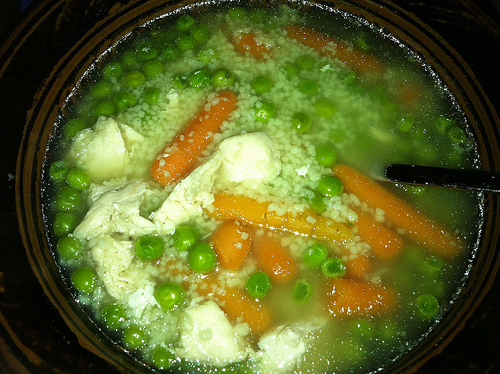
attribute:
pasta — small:
[71, 110, 315, 372]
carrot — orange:
[145, 82, 243, 190]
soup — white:
[33, 7, 482, 372]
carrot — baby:
[338, 179, 433, 244]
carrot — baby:
[243, 200, 344, 253]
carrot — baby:
[316, 279, 399, 305]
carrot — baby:
[155, 115, 222, 182]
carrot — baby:
[203, 226, 263, 268]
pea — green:
[188, 245, 216, 271]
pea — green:
[244, 264, 279, 306]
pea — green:
[146, 343, 176, 370]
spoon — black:
[359, 136, 498, 205]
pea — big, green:
[184, 245, 220, 276]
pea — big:
[171, 219, 200, 250]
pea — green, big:
[133, 230, 163, 261]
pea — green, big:
[53, 233, 89, 265]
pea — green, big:
[46, 207, 78, 232]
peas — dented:
[307, 244, 324, 264]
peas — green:
[49, 165, 124, 299]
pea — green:
[118, 70, 146, 95]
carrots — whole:
[220, 156, 410, 333]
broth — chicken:
[45, 5, 492, 364]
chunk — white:
[65, 114, 137, 178]